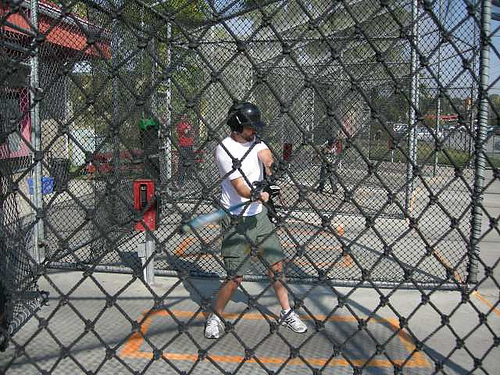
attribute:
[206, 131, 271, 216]
t-shirt — white 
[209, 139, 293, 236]
shirt — white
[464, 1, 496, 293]
pole — tall, metal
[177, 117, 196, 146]
shirt — red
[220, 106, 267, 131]
helmet — black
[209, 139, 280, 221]
shirt — white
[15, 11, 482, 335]
cages — down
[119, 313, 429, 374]
batter's box — orange , painted 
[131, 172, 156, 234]
box — red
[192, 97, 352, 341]
man — wearing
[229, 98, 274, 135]
helmet — black 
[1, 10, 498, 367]
fence — chain link, black , metal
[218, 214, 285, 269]
shorts — cargo 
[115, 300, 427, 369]
box — yellow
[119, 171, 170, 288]
box — red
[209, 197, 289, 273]
shorts — green 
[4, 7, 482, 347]
cage — batting